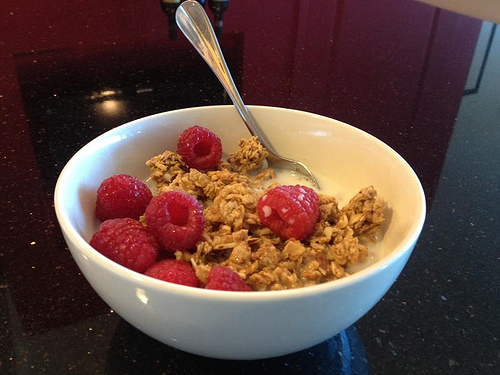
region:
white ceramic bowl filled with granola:
[46, 103, 436, 362]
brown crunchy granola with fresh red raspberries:
[91, 124, 386, 286]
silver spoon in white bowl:
[175, 1, 338, 203]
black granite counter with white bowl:
[6, 0, 496, 365]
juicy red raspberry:
[140, 185, 209, 250]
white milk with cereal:
[140, 121, 391, 290]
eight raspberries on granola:
[95, 119, 325, 289]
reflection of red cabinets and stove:
[11, 0, 497, 170]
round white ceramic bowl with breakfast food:
[51, 89, 430, 366]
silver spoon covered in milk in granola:
[176, 5, 336, 189]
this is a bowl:
[28, 60, 459, 362]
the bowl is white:
[39, 82, 441, 374]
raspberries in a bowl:
[82, 115, 339, 302]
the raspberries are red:
[80, 125, 328, 288]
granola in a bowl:
[143, 117, 383, 299]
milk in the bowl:
[225, 137, 345, 206]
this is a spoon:
[160, 0, 314, 191]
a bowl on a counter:
[0, 5, 498, 371]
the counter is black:
[5, 3, 494, 365]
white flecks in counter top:
[9, 15, 499, 357]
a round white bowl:
[53, 102, 425, 361]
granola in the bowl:
[146, 134, 385, 291]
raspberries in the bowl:
[88, 123, 320, 289]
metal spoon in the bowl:
[174, 0, 320, 190]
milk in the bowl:
[133, 165, 382, 275]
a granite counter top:
[1, 0, 498, 374]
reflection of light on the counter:
[97, 91, 121, 114]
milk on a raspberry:
[260, 194, 294, 226]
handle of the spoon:
[174, 0, 246, 110]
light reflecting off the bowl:
[135, 280, 148, 306]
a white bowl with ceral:
[119, 79, 361, 361]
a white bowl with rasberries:
[104, 99, 396, 361]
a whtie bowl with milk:
[146, 125, 462, 309]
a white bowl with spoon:
[97, 118, 406, 352]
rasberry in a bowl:
[264, 169, 314, 240]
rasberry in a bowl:
[197, 253, 268, 320]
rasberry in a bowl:
[179, 118, 204, 155]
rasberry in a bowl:
[147, 197, 205, 245]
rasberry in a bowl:
[166, 258, 190, 303]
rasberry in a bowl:
[109, 218, 148, 263]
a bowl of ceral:
[47, 45, 444, 348]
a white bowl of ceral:
[52, 81, 387, 368]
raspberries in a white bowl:
[130, 105, 460, 339]